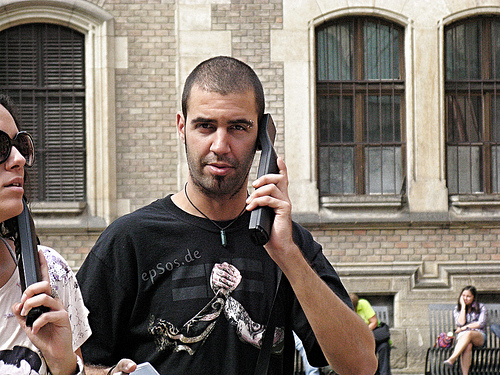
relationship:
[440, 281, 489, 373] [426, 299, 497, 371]
woman bench sitting on a bench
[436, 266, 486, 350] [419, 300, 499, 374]
lady on bench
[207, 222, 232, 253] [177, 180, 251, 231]
pendant on black necklace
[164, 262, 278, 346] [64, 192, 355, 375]
decal on black t-shirt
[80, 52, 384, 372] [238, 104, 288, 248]
man on phone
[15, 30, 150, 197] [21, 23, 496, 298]
window on building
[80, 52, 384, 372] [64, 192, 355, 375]
man wearing black t-shirt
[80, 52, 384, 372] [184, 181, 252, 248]
man wearing black necklace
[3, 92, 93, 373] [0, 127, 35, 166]
woman wearing sunglasses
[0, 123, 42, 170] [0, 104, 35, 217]
sunglasses are on face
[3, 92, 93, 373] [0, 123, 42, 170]
woman wearing sunglasses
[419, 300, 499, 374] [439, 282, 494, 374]
bench under lady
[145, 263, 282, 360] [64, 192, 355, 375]
design on black t-shirt